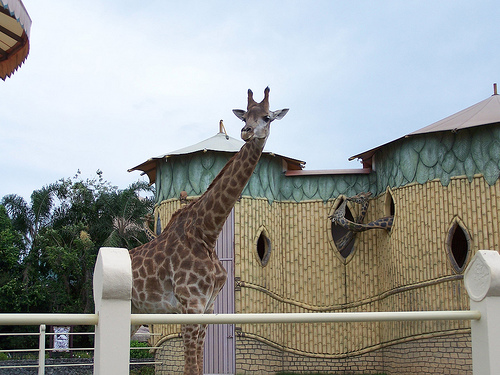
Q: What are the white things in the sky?
A: Clouds.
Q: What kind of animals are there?
A: Giraffes.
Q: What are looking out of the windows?
A: Giraffes.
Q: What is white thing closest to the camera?
A: A railing.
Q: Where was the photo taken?
A: A zoo.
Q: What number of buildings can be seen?
A: One.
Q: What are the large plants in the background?
A: Trees.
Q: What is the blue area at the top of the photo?
A: The sky.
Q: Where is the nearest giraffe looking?
A: To the left.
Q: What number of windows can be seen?
A: Four.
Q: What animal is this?
A: Giraffe.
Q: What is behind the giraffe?
A: Housing for giraffe.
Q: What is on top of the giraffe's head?
A: Horns.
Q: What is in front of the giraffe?
A: Guard rail.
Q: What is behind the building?
A: Palm trees.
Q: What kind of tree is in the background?
A: Palm tree.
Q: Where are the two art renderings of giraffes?
A: Building window.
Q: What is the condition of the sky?
A: Hazy.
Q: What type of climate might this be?
A: Tropical.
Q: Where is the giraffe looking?
A: It's right.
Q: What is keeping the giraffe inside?
A: A fence.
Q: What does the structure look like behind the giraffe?
A: A castle.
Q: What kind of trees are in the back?
A: Palm trees.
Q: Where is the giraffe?
A: In a zoo.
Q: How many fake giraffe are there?
A: Two.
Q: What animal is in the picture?
A: Giraffe.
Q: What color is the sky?
A: Blue.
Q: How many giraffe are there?
A: One.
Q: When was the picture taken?
A: Daytime.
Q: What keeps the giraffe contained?
A: The fence.